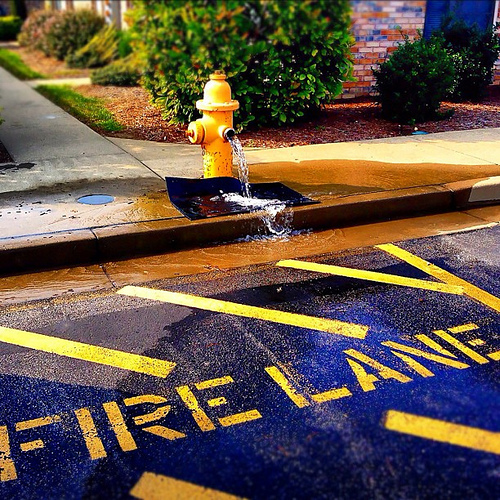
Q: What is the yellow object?
A: A fire hydrant.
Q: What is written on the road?
A: Fire lane.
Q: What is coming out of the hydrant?
A: Water.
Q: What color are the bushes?
A: Green.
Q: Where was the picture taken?
A: On the street.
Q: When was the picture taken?
A: Daytime.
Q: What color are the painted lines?
A: Yellow.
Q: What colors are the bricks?
A: Red and Black.